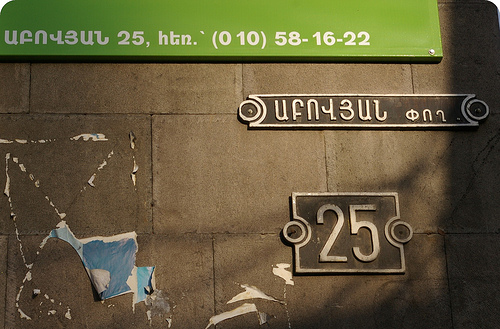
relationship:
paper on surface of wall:
[45, 215, 159, 313] [2, 3, 498, 326]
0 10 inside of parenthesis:
[219, 28, 261, 48] [207, 26, 219, 50]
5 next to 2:
[346, 200, 387, 264] [313, 202, 351, 266]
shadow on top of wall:
[24, 4, 499, 328] [2, 3, 498, 326]